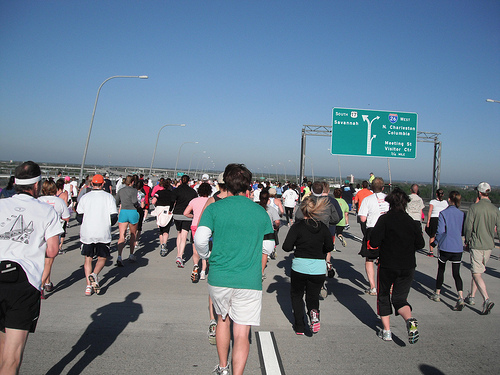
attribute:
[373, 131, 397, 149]
street sign — green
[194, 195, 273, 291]
shirt — green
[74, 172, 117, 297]
jogger — human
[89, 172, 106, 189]
head — human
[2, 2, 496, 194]
sky — blue, clear, cloudless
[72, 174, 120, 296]
person — wearing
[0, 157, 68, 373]
person — wearing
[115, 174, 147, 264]
person — wearing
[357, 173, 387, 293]
person — wearing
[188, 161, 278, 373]
person — wearing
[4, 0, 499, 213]
sky — blue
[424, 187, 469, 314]
woman — wearing